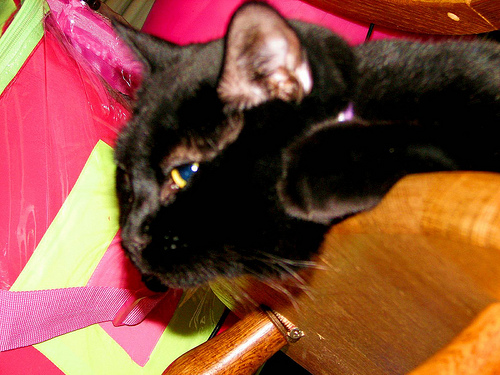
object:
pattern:
[2, 0, 230, 375]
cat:
[109, 1, 500, 321]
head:
[90, 0, 375, 322]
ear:
[92, 0, 176, 78]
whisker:
[244, 249, 358, 322]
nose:
[120, 225, 145, 262]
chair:
[156, 170, 500, 375]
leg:
[155, 312, 290, 375]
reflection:
[165, 154, 205, 188]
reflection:
[244, 323, 276, 358]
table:
[252, 170, 499, 374]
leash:
[1, 286, 181, 353]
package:
[1, 1, 500, 375]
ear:
[213, 0, 320, 107]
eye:
[162, 158, 211, 192]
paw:
[276, 123, 413, 227]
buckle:
[112, 281, 177, 329]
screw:
[262, 300, 308, 345]